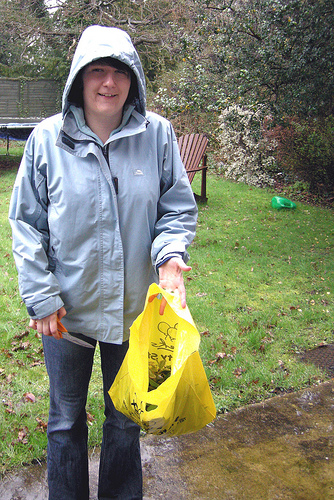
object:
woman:
[8, 23, 197, 498]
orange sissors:
[55, 315, 67, 338]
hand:
[29, 307, 65, 338]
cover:
[266, 190, 299, 210]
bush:
[214, 101, 282, 197]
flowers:
[208, 102, 285, 181]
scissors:
[56, 320, 94, 349]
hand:
[152, 250, 194, 312]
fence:
[0, 67, 58, 130]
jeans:
[40, 329, 143, 498]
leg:
[40, 338, 93, 498]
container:
[264, 194, 296, 218]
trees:
[290, 0, 334, 186]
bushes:
[236, 113, 272, 175]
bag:
[106, 281, 218, 437]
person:
[6, 22, 199, 497]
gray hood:
[59, 23, 152, 130]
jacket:
[7, 108, 198, 345]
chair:
[176, 133, 207, 208]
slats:
[177, 131, 208, 183]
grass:
[215, 189, 331, 376]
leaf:
[215, 352, 222, 358]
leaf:
[209, 343, 216, 351]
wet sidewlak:
[144, 437, 332, 498]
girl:
[5, 25, 198, 499]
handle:
[54, 319, 66, 336]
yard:
[0, 142, 324, 466]